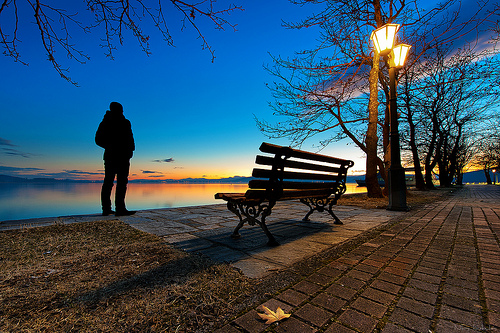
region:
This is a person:
[79, 90, 180, 264]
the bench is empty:
[203, 138, 363, 230]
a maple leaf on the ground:
[243, 290, 298, 330]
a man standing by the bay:
[77, 87, 154, 217]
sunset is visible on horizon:
[136, 127, 243, 196]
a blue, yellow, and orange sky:
[139, 122, 242, 219]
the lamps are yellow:
[360, 19, 425, 79]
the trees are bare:
[265, 25, 355, 158]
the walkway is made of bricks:
[345, 217, 492, 331]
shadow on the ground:
[108, 215, 343, 310]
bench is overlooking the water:
[209, 132, 365, 252]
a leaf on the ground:
[253, 301, 293, 325]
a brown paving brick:
[310, 289, 344, 315]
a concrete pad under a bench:
[125, 192, 398, 281]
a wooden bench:
[210, 140, 354, 247]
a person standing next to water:
[93, 100, 133, 217]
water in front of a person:
[0, 178, 387, 219]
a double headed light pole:
[372, 20, 418, 213]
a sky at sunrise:
[0, 0, 497, 178]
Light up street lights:
[371, 19, 414, 211]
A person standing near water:
[91, 97, 141, 221]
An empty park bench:
[213, 140, 348, 244]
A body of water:
[2, 165, 429, 200]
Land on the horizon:
[6, 168, 488, 185]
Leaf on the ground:
[256, 302, 291, 326]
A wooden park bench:
[215, 138, 350, 201]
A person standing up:
[92, 95, 141, 216]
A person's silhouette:
[93, 98, 141, 220]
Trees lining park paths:
[311, 8, 473, 196]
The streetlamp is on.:
[386, 38, 424, 220]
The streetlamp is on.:
[361, 10, 399, 214]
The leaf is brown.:
[241, 290, 302, 331]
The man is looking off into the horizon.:
[53, 14, 497, 222]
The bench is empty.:
[204, 128, 357, 248]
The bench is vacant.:
[206, 122, 363, 257]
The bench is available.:
[196, 128, 362, 261]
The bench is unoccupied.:
[202, 124, 365, 257]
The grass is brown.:
[0, 170, 257, 332]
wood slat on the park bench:
[255, 142, 356, 167]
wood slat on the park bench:
[250, 153, 347, 178]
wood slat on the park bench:
[251, 166, 343, 184]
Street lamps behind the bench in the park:
[336, 9, 453, 111]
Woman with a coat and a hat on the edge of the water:
[89, 86, 172, 250]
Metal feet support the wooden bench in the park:
[186, 175, 340, 253]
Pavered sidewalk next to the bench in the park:
[198, 136, 487, 328]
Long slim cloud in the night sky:
[221, 7, 498, 112]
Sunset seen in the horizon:
[7, 102, 495, 207]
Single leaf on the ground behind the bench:
[246, 279, 307, 329]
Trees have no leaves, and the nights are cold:
[36, 1, 494, 261]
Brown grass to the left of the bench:
[7, 190, 263, 330]